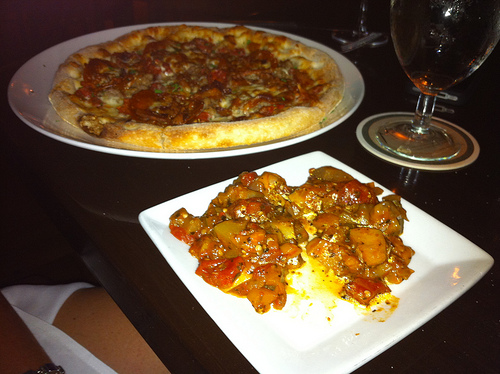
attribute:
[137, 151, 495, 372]
plate — white, square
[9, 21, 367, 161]
plate — white, rounded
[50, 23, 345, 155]
pizza — browned, small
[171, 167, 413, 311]
food — multi-colored, yellow, red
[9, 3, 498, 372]
table — well laid, brown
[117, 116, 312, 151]
crust — golden brown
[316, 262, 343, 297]
sauce — yellow